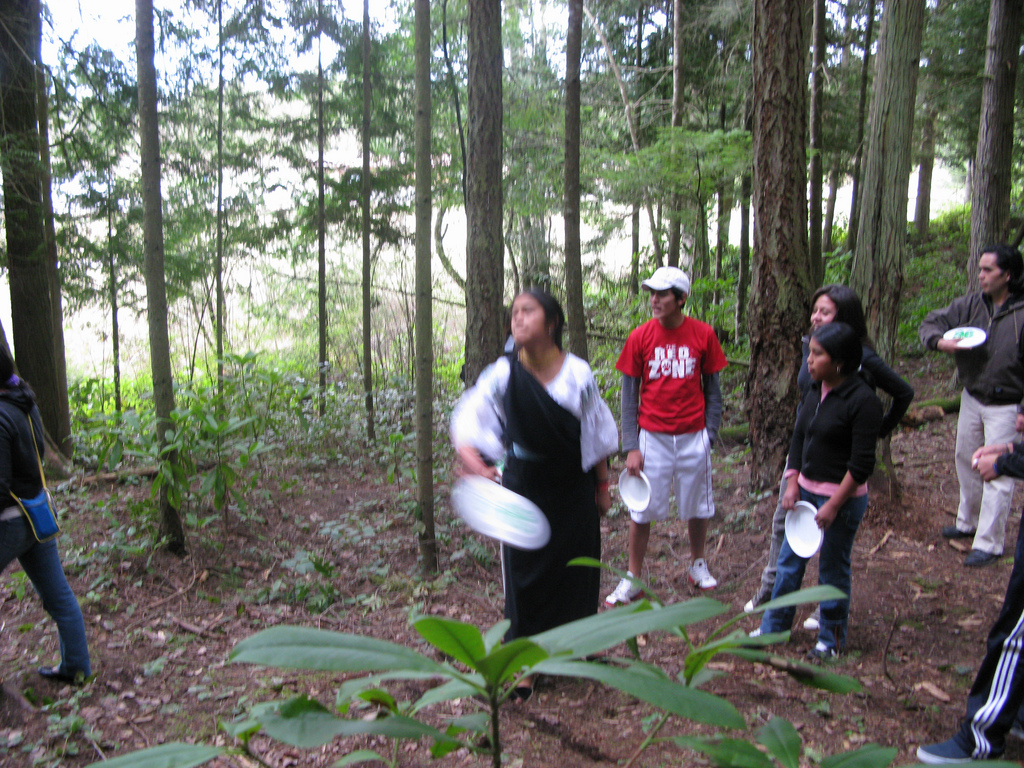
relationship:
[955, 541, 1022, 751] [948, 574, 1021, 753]
leg has pants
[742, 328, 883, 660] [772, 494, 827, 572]
child holding frisbee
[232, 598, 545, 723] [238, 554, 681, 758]
leaves on plant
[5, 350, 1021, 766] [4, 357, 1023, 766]
branches on ground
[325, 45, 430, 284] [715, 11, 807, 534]
leaves on tree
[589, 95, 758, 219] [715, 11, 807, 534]
leaves on tree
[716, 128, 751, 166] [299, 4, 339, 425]
leaf on tree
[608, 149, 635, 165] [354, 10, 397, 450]
leaf on tree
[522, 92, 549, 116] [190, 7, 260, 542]
leaf on tree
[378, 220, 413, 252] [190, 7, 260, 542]
leaf on tree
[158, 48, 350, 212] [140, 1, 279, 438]
green leaves on tree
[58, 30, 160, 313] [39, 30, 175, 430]
leaves on tree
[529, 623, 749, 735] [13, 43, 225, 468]
leaves on tree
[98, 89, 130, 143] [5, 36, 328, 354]
green leaves on tree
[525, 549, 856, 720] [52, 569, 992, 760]
leaves on tree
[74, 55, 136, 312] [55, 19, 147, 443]
green leaves on tree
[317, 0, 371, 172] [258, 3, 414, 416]
green leaves on tree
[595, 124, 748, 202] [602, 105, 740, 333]
green leaves on tree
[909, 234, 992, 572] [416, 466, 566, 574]
man throwing frisbee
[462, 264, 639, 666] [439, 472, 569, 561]
lady throwing frisbee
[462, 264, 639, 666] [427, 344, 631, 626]
lady wearing dress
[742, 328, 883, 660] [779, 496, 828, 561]
child holding frisbee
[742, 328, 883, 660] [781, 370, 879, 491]
child wearing sweater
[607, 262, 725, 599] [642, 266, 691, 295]
man wearing cap